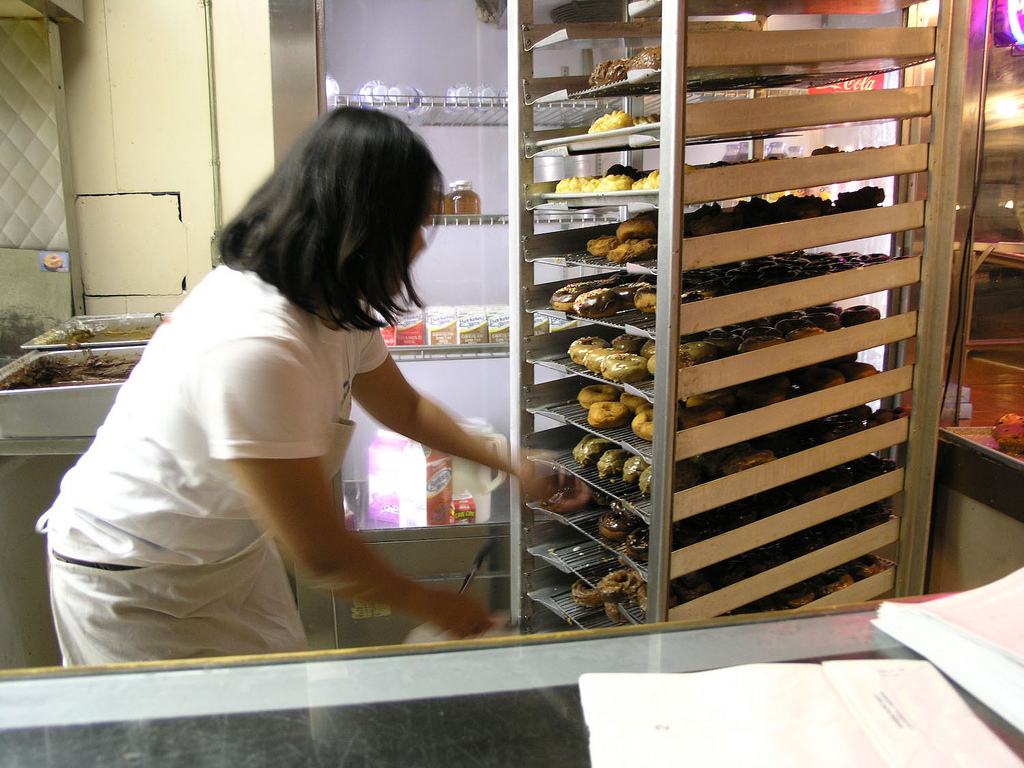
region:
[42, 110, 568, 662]
woman pulling donuts off a cart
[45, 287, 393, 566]
white shirt on the woman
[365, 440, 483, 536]
cartons of milk in the refridgerator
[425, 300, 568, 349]
cartons of chocolate milk in the refridgerator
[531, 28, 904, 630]
donuts on a metal cart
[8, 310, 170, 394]
pans full of chocolate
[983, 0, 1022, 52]
pink neon sign in the window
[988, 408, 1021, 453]
muffin on the metal counter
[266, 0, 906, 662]
large refridgerator in the bakery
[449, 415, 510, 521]
clear plastic pitcher in the refrigerator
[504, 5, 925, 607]
A variety of donuts.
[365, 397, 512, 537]
Milk and cream stored.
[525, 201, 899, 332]
A rack of chocolate donuts.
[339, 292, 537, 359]
Regular and chocolate milk.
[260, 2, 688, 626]
A refriderator full of milk.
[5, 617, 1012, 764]
A counter with paper bags.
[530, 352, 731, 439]
A rack of uncoated donuts.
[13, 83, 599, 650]
A worker in an apron.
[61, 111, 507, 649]
woman with a apron on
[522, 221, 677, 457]
pastry on a shelf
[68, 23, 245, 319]
A beige kitchen wall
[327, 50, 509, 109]
Cooking supplies on a shelf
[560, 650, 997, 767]
Paper on a counter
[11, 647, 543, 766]
stainless steel table top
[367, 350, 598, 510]
Lady hand on the pastry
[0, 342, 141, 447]
A pan on the counter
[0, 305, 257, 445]
dirty trays on side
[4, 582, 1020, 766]
paper on counter top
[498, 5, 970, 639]
donuts on tray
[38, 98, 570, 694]
woman wearing white shirt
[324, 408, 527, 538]
milk on side tray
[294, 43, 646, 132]
cups on top shelve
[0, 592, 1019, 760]
counter top is black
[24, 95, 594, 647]
woman have white apron on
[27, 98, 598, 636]
woman holding a pen in hand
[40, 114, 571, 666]
woman working in a kitchen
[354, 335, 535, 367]
rack holding milk cartons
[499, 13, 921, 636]
racks of donuts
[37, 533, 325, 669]
apron on a woman's lower torso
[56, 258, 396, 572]
white shirt of a woman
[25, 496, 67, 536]
string of an apron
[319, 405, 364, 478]
front bib of the apron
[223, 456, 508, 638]
right arm of the woman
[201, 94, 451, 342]
dark hair of the woman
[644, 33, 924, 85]
baking tray on doughnut cart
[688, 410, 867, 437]
baking tray on doughnut cart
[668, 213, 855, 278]
baking tray on doughnut cart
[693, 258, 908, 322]
baking tray on doughnut cart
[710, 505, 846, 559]
baking tray on doughnut cart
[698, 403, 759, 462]
baking tray on doughnut cartbaking tray on doughnut cart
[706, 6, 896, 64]
baking tray on doughnut cart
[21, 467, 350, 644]
the womans hips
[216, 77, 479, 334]
the womans head above shoulders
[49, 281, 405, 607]
the womans shirt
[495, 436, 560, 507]
the womans hand at end of arm